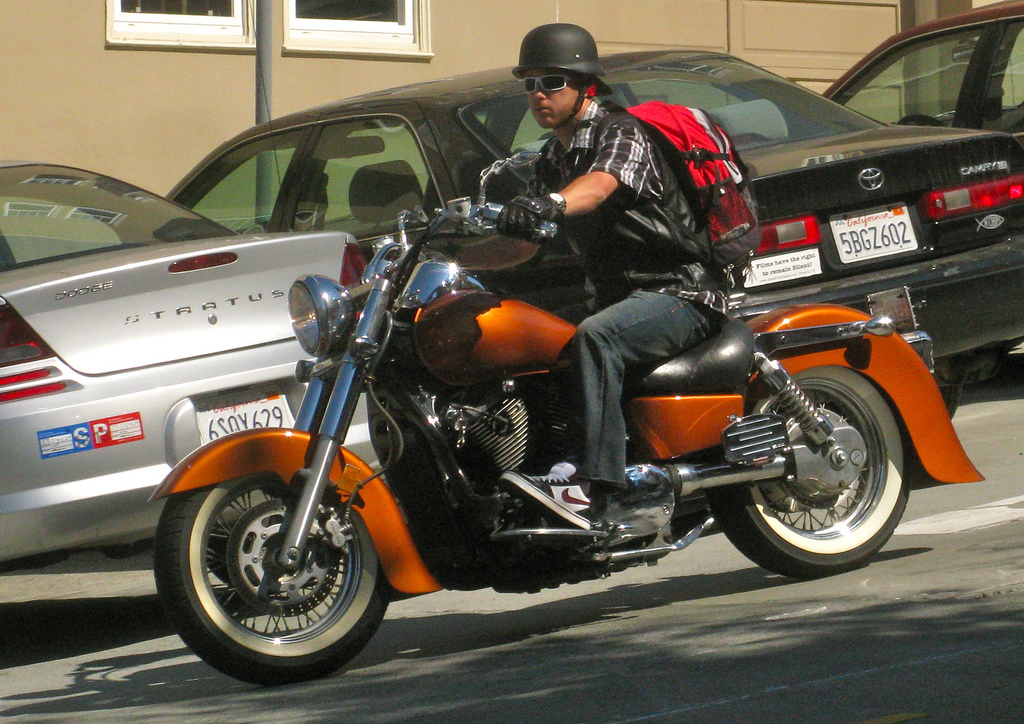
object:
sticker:
[36, 411, 145, 460]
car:
[0, 159, 410, 562]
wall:
[90, 59, 194, 166]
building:
[0, 0, 558, 198]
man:
[433, 22, 762, 530]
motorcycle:
[147, 151, 987, 687]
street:
[0, 399, 1022, 721]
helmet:
[510, 23, 605, 79]